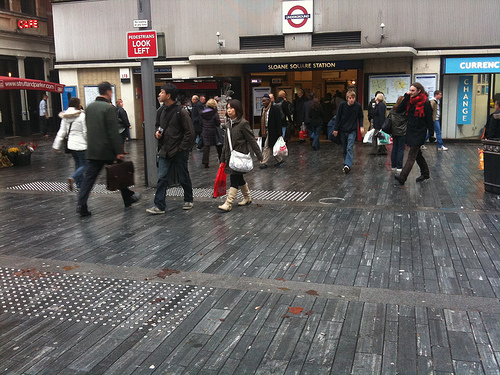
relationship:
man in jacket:
[258, 93, 281, 168] [259, 100, 283, 144]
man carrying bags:
[258, 93, 281, 168] [272, 136, 288, 159]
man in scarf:
[387, 79, 439, 189] [404, 95, 430, 114]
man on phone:
[387, 79, 439, 189] [404, 88, 412, 102]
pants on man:
[149, 156, 195, 214] [144, 81, 195, 215]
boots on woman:
[214, 185, 239, 217] [209, 92, 272, 208]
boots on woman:
[238, 180, 254, 205] [209, 92, 272, 208]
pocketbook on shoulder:
[227, 147, 257, 175] [231, 111, 256, 134]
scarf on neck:
[408, 97, 428, 119] [411, 93, 426, 100]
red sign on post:
[123, 32, 158, 59] [136, 2, 168, 188]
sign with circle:
[282, 1, 314, 34] [286, 2, 309, 27]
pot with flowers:
[5, 145, 35, 170] [6, 144, 18, 151]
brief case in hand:
[105, 160, 134, 191] [115, 150, 125, 162]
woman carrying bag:
[216, 98, 264, 212] [209, 156, 227, 195]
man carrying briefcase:
[76, 81, 142, 217] [104, 157, 136, 190]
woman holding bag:
[216, 98, 264, 212] [210, 161, 227, 198]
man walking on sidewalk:
[393, 82, 436, 185] [333, 210, 499, 365]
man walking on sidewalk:
[330, 88, 366, 174] [333, 210, 499, 365]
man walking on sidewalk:
[150, 79, 198, 224] [333, 210, 499, 365]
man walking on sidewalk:
[76, 81, 142, 217] [333, 210, 499, 365]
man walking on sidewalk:
[427, 85, 454, 152] [333, 210, 499, 365]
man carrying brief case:
[81, 76, 142, 216] [100, 149, 133, 192]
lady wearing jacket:
[48, 95, 89, 190] [51, 105, 92, 152]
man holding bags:
[260, 93, 285, 169] [253, 135, 288, 160]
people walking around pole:
[50, 78, 269, 220] [120, 17, 202, 214]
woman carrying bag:
[220, 91, 272, 201] [212, 162, 227, 199]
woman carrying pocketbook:
[220, 91, 272, 201] [226, 127, 254, 173]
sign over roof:
[282, 1, 314, 34] [49, 1, 494, 75]